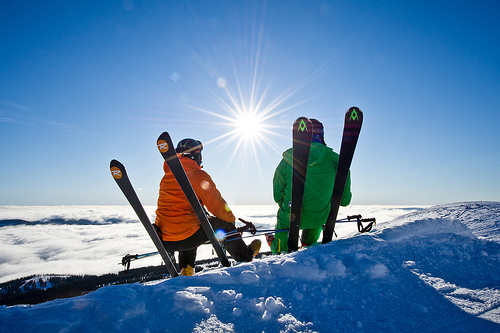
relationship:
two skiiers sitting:
[109, 117, 405, 200] [142, 222, 343, 258]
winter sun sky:
[334, 258, 403, 304] [350, 14, 433, 110]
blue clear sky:
[30, 45, 69, 65] [350, 14, 433, 110]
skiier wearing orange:
[144, 123, 214, 207] [155, 196, 184, 212]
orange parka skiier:
[155, 196, 184, 212] [144, 123, 214, 207]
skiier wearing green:
[144, 123, 214, 207] [313, 167, 328, 214]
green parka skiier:
[313, 167, 328, 214] [144, 123, 214, 207]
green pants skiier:
[313, 167, 328, 214] [144, 123, 214, 207]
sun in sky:
[194, 102, 286, 151] [350, 14, 433, 110]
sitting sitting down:
[152, 222, 216, 252] [160, 258, 331, 300]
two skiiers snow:
[109, 117, 405, 200] [208, 273, 261, 332]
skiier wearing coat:
[144, 123, 214, 207] [274, 144, 346, 221]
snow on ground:
[208, 273, 261, 332] [79, 221, 182, 265]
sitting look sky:
[152, 222, 216, 252] [350, 14, 433, 110]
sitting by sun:
[152, 222, 216, 252] [194, 102, 286, 151]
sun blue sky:
[194, 102, 286, 151] [350, 14, 433, 110]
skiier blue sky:
[144, 123, 214, 207] [350, 14, 433, 110]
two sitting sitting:
[109, 117, 405, 200] [152, 222, 216, 252]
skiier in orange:
[144, 123, 214, 207] [155, 196, 184, 212]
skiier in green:
[144, 123, 214, 207] [313, 167, 328, 214]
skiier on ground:
[144, 123, 214, 207] [79, 221, 182, 265]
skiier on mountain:
[144, 123, 214, 207] [394, 206, 455, 253]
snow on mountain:
[208, 273, 261, 332] [394, 206, 455, 253]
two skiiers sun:
[109, 117, 405, 200] [194, 102, 286, 151]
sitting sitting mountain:
[152, 222, 216, 252] [394, 206, 455, 253]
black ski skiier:
[150, 132, 199, 197] [144, 123, 214, 207]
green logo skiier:
[313, 167, 328, 214] [144, 123, 214, 207]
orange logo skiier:
[155, 196, 184, 212] [144, 123, 214, 207]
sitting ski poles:
[152, 222, 216, 252] [234, 219, 270, 251]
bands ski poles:
[111, 250, 149, 280] [234, 219, 270, 251]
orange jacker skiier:
[155, 196, 184, 212] [144, 123, 214, 207]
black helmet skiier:
[150, 132, 199, 197] [144, 123, 214, 207]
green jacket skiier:
[313, 167, 328, 214] [144, 123, 214, 207]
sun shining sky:
[194, 102, 286, 151] [350, 14, 433, 110]